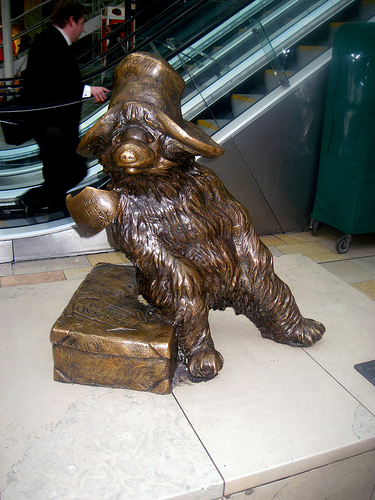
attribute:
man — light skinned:
[19, 5, 110, 217]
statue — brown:
[122, 69, 168, 135]